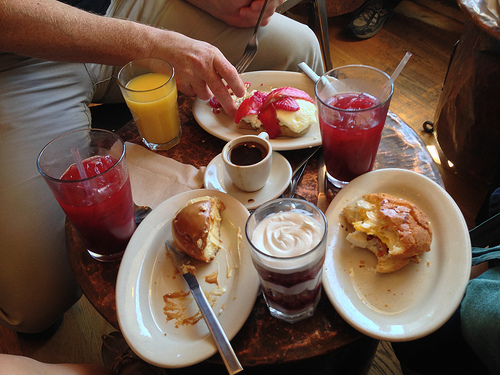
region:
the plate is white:
[353, 296, 461, 356]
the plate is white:
[396, 239, 423, 317]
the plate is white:
[367, 253, 404, 363]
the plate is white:
[370, 325, 393, 367]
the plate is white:
[354, 253, 414, 315]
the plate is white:
[407, 239, 419, 342]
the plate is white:
[359, 285, 390, 357]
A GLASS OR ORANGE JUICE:
[115, 53, 187, 160]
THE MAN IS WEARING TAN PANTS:
[0, 1, 332, 348]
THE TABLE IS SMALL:
[50, 65, 447, 372]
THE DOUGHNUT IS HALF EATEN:
[165, 197, 231, 259]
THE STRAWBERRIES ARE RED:
[228, 83, 315, 151]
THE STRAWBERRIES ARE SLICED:
[231, 83, 318, 145]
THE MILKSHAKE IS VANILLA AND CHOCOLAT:
[249, 192, 331, 328]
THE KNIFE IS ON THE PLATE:
[161, 238, 246, 373]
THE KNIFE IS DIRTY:
[161, 240, 251, 374]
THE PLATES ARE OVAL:
[113, 67, 478, 373]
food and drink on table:
[43, 40, 476, 350]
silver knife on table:
[162, 252, 242, 373]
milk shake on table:
[246, 197, 330, 339]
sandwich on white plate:
[341, 200, 420, 281]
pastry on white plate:
[232, 87, 309, 133]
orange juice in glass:
[118, 63, 183, 143]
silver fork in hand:
[231, 13, 274, 80]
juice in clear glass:
[48, 135, 147, 247]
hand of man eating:
[166, 38, 248, 118]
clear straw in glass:
[371, 51, 414, 96]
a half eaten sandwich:
[335, 175, 430, 295]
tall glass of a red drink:
[291, 47, 403, 202]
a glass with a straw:
[15, 114, 138, 259]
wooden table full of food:
[70, 45, 453, 342]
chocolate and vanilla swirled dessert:
[218, 200, 345, 361]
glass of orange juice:
[100, 36, 212, 155]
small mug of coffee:
[220, 123, 315, 214]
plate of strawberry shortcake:
[207, 56, 322, 151]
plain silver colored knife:
[146, 226, 256, 371]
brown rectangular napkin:
[93, 127, 217, 222]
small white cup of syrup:
[222, 131, 271, 193]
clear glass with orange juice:
[118, 56, 183, 148]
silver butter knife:
[163, 238, 241, 373]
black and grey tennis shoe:
[346, 3, 392, 40]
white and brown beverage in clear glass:
[248, 196, 321, 319]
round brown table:
[63, 73, 448, 365]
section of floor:
[286, 6, 444, 163]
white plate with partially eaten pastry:
[323, 166, 472, 338]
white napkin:
[103, 138, 207, 213]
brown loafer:
[97, 326, 145, 371]